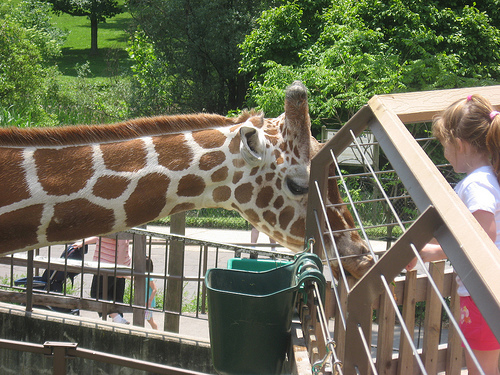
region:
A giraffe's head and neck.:
[1, 78, 380, 287]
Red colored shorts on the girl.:
[447, 283, 498, 356]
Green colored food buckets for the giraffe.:
[195, 243, 332, 374]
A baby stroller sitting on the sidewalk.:
[7, 239, 87, 298]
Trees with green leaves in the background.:
[3, 2, 498, 73]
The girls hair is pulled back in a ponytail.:
[426, 93, 498, 175]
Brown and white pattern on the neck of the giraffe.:
[10, 141, 217, 205]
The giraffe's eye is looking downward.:
[275, 158, 313, 203]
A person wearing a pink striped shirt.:
[88, 235, 130, 272]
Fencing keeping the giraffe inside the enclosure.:
[316, 161, 425, 371]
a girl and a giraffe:
[211, 46, 492, 346]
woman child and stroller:
[37, 134, 187, 319]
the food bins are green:
[179, 204, 360, 370]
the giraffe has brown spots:
[222, 63, 377, 260]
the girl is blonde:
[401, 46, 495, 256]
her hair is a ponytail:
[428, 87, 494, 195]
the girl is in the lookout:
[211, 40, 494, 308]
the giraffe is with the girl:
[183, 39, 496, 361]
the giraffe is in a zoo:
[129, 37, 478, 340]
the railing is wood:
[237, 68, 469, 313]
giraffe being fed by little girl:
[13, 75, 379, 282]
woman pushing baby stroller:
[86, 230, 131, 328]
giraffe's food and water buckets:
[197, 251, 321, 373]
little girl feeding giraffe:
[405, 92, 499, 362]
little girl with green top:
[139, 253, 161, 328]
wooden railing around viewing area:
[306, 84, 492, 374]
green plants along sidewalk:
[155, 292, 213, 313]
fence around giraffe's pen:
[7, 225, 285, 341]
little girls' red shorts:
[446, 287, 497, 362]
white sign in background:
[325, 123, 371, 179]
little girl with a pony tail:
[432, 104, 499, 369]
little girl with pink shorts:
[433, 103, 498, 373]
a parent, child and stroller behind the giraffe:
[12, 236, 157, 306]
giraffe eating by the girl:
[2, 90, 374, 276]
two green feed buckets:
[215, 254, 314, 374]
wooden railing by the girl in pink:
[300, 89, 498, 367]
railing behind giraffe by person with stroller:
[8, 237, 299, 374]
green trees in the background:
[4, 3, 498, 213]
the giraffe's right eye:
[289, 180, 309, 195]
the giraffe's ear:
[241, 125, 263, 161]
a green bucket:
[207, 265, 289, 371]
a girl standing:
[439, 113, 498, 200]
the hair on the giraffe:
[56, 127, 132, 144]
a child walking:
[141, 259, 166, 322]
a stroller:
[60, 248, 87, 259]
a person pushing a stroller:
[93, 236, 132, 281]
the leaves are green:
[130, 45, 186, 105]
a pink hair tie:
[486, 110, 499, 120]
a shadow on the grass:
[63, 46, 125, 76]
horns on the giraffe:
[279, 82, 314, 147]